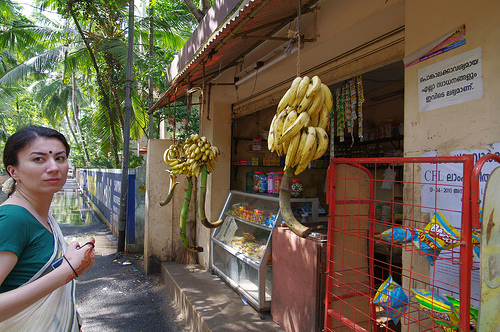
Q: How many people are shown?
A: One.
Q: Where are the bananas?
A: Hanging.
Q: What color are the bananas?
A: Yellow.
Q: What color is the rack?
A: Red.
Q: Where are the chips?
A: On rack.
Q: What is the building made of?
A: Stone.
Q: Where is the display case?
A: Front of store.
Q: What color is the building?
A: Tan.